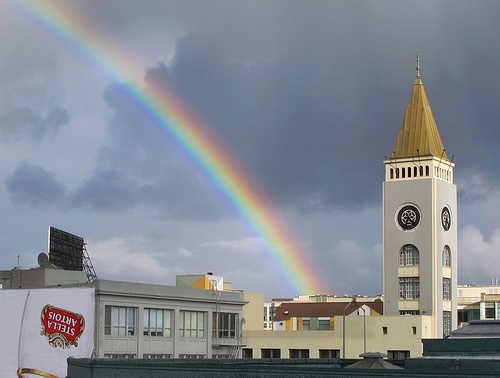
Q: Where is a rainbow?
A: In the sky.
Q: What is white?
A: Buildings.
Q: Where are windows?
A: On buildings.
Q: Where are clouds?
A: In the sky.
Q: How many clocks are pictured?
A: Two.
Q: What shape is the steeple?
A: Triangle.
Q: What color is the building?
A: Beige.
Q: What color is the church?
A: Grey.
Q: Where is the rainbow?
A: Above the building.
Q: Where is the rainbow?
A: In front of the clouds.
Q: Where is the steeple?
A: On the right.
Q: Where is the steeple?
A: On top of the tower.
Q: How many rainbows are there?
A: One.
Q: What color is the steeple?
A: Gold.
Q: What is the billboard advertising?
A: A beer.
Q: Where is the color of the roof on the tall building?
A: Yellow.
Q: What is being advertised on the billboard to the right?
A: Stella Artois.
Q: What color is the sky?
A: Dark gray.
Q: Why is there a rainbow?
A: It has rained.